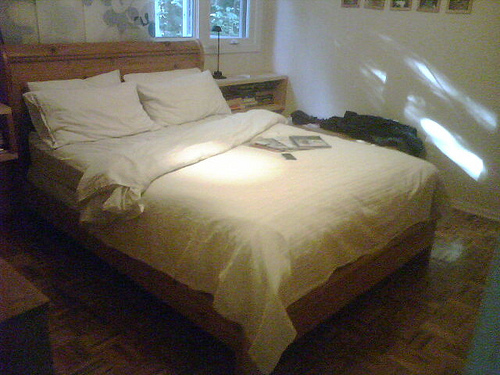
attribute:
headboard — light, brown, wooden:
[2, 33, 207, 139]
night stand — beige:
[216, 69, 293, 119]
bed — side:
[1, 36, 447, 372]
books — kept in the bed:
[253, 130, 330, 157]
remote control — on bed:
[277, 148, 297, 163]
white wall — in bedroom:
[300, 10, 470, 114]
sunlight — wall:
[351, 15, 484, 177]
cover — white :
[65, 96, 433, 346]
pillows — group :
[42, 55, 235, 139]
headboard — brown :
[3, 25, 215, 144]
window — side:
[151, 1, 260, 43]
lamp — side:
[197, 13, 228, 83]